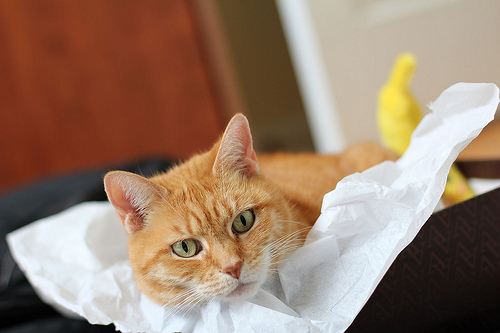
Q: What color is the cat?
A: Orange.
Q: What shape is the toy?
A: Banana shaped.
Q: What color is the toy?
A: Yellow.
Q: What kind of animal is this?
A: Cat.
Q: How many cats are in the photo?
A: One.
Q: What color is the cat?
A: Tan and white.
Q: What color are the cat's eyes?
A: Yellow and black.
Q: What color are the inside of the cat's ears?
A: Pink.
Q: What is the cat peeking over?
A: White tissue paper.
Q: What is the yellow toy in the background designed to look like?
A: Banana.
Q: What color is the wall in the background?
A: Tan.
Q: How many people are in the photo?
A: None.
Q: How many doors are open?
A: One.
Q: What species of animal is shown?
A: Cat.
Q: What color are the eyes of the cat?
A: Green.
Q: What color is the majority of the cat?
A: Orange.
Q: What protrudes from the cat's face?
A: Whiskers.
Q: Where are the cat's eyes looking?
A: The camera.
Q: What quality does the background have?
A: Blurry.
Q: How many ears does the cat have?
A: Two.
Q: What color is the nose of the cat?
A: Pink.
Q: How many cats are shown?
A: One.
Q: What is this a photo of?
A: A cute cat.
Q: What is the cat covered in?
A: Fur.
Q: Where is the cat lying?
A: On white paper.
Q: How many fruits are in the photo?
A: One.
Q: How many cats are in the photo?
A: One.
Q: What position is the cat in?
A: Lying down position.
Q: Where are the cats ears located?
A: Top of its head.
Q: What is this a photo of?
A: Cat lying on white paper.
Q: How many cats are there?
A: 1.